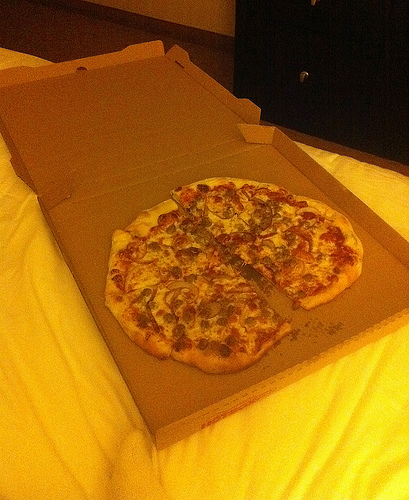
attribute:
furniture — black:
[232, 0, 407, 177]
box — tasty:
[31, 53, 397, 446]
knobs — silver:
[296, 1, 314, 89]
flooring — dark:
[36, 13, 222, 72]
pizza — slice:
[173, 179, 286, 244]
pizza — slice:
[171, 258, 290, 370]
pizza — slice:
[127, 195, 209, 256]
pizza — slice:
[100, 225, 218, 305]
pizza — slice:
[106, 258, 223, 354]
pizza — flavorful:
[73, 167, 355, 378]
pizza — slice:
[227, 215, 335, 253]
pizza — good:
[101, 170, 359, 321]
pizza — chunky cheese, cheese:
[101, 191, 361, 337]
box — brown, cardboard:
[0, 32, 409, 451]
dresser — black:
[234, 1, 408, 174]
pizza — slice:
[121, 191, 228, 254]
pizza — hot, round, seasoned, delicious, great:
[102, 174, 364, 374]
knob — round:
[292, 65, 318, 95]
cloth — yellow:
[227, 396, 405, 498]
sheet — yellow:
[0, 48, 408, 498]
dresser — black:
[242, 16, 398, 124]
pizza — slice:
[141, 202, 211, 252]